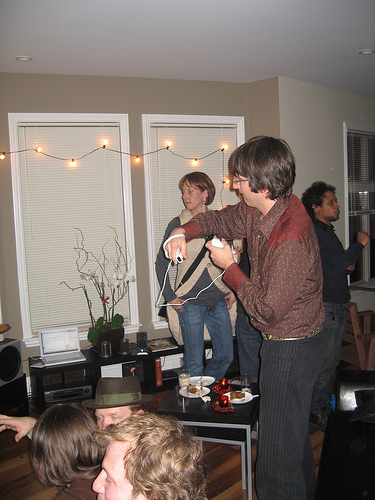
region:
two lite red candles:
[208, 374, 234, 415]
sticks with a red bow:
[66, 215, 135, 359]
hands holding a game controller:
[158, 208, 239, 299]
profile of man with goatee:
[301, 166, 350, 228]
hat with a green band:
[80, 367, 164, 425]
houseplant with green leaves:
[79, 308, 126, 349]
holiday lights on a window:
[4, 107, 226, 165]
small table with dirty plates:
[162, 365, 260, 490]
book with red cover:
[150, 350, 167, 391]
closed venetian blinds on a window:
[16, 113, 134, 325]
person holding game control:
[201, 131, 327, 358]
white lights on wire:
[63, 131, 202, 173]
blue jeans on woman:
[178, 292, 242, 383]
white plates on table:
[177, 372, 220, 408]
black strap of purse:
[179, 253, 206, 289]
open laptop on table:
[33, 325, 92, 374]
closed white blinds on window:
[38, 171, 107, 238]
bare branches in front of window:
[68, 223, 123, 280]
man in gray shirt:
[311, 179, 363, 282]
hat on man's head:
[80, 371, 160, 419]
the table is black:
[89, 343, 248, 450]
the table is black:
[161, 392, 258, 450]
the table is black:
[159, 345, 239, 486]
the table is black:
[88, 265, 267, 494]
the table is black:
[187, 357, 275, 489]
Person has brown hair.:
[250, 142, 299, 214]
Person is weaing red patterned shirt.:
[256, 262, 303, 320]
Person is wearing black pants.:
[267, 363, 288, 427]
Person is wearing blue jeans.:
[173, 320, 219, 350]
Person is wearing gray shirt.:
[190, 283, 214, 308]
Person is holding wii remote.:
[162, 221, 234, 274]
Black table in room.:
[192, 406, 233, 442]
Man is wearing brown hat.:
[87, 380, 141, 423]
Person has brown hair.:
[52, 425, 101, 470]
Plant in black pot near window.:
[72, 284, 174, 333]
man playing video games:
[150, 139, 339, 390]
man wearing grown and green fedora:
[81, 369, 157, 433]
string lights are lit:
[1, 111, 235, 208]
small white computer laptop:
[27, 324, 95, 367]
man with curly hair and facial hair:
[296, 117, 356, 298]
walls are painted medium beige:
[1, 70, 355, 207]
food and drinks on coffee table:
[155, 368, 268, 443]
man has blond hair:
[77, 411, 211, 498]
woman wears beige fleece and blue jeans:
[150, 166, 238, 369]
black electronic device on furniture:
[30, 370, 103, 414]